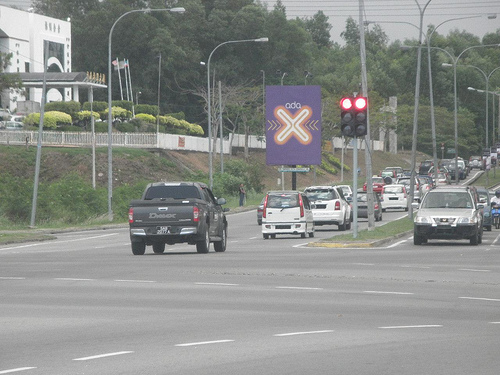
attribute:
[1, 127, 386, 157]
fence — white, picket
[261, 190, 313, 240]
vehicle — white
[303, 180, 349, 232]
vehicle — white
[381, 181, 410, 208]
vehicle — white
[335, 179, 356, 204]
vehicle — white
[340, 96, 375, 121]
street light — red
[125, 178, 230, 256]
truck — driving, charcoal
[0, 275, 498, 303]
lines — white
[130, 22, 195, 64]
leaves — green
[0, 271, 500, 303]
line — white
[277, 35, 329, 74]
leaves — green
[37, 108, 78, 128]
bush — yellow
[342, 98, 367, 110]
signal — red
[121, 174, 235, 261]
truck — driving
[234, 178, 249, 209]
person — standing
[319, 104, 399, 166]
light — red, lit up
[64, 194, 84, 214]
grass — growing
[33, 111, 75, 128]
bush — yellow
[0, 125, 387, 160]
fence — white